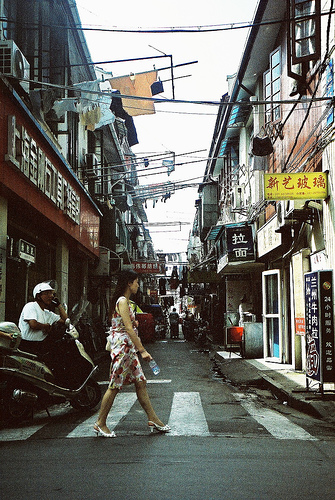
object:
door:
[261, 268, 282, 363]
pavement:
[0, 432, 335, 499]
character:
[311, 273, 317, 288]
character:
[310, 288, 319, 303]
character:
[311, 326, 317, 338]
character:
[233, 244, 249, 259]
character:
[232, 231, 247, 246]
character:
[133, 263, 140, 271]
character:
[140, 261, 147, 271]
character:
[152, 261, 159, 270]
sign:
[225, 225, 257, 266]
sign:
[133, 260, 160, 269]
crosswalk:
[0, 389, 335, 444]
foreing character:
[320, 271, 335, 379]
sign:
[316, 268, 335, 385]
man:
[17, 278, 85, 389]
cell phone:
[50, 297, 58, 305]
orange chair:
[226, 325, 242, 358]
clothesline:
[251, 134, 274, 158]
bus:
[303, 268, 335, 397]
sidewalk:
[0, 330, 335, 499]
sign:
[263, 170, 330, 203]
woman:
[91, 271, 172, 435]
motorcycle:
[0, 301, 104, 426]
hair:
[106, 269, 138, 324]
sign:
[291, 271, 335, 400]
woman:
[168, 305, 180, 339]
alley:
[0, 0, 335, 499]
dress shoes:
[95, 418, 116, 437]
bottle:
[145, 352, 161, 376]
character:
[311, 314, 319, 328]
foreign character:
[303, 271, 318, 379]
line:
[162, 386, 212, 436]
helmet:
[32, 278, 58, 302]